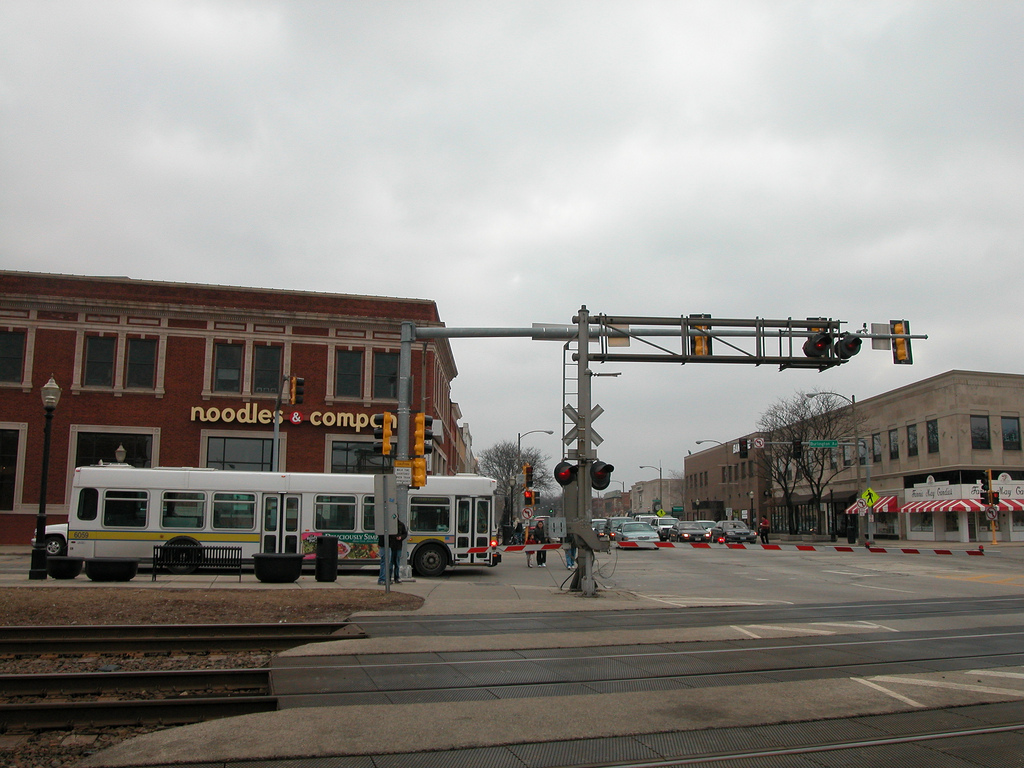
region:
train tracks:
[98, 671, 219, 710]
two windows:
[89, 337, 166, 398]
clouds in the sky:
[510, 136, 763, 295]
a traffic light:
[882, 311, 921, 366]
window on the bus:
[162, 494, 220, 529]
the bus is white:
[69, 468, 172, 551]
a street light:
[39, 362, 66, 514]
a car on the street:
[613, 510, 658, 548]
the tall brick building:
[2, 266, 480, 548]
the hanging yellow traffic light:
[375, 409, 394, 464]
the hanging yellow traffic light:
[409, 407, 433, 455]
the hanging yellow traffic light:
[408, 458, 431, 485]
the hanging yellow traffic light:
[689, 310, 713, 358]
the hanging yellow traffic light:
[889, 319, 915, 364]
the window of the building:
[883, 423, 899, 463]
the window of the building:
[902, 420, 919, 458]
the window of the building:
[925, 414, 941, 460]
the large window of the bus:
[102, 487, 150, 530]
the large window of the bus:
[159, 491, 208, 536]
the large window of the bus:
[215, 487, 260, 530]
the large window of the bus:
[317, 494, 360, 532]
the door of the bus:
[258, 487, 281, 564]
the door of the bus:
[282, 484, 302, 564]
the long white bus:
[65, 456, 502, 571]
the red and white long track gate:
[446, 535, 994, 567]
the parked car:
[667, 513, 718, 543]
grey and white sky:
[518, 5, 703, 187]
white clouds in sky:
[427, 19, 703, 187]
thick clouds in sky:
[423, 27, 654, 263]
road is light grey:
[674, 565, 887, 699]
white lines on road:
[690, 572, 900, 680]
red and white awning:
[817, 476, 1021, 527]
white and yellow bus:
[64, 425, 451, 575]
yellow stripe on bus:
[49, 507, 366, 565]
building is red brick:
[10, 287, 426, 553]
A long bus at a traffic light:
[71, 467, 502, 567]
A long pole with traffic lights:
[424, 320, 936, 368]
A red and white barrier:
[465, 538, 1012, 561]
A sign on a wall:
[193, 398, 405, 438]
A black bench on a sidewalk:
[147, 540, 250, 580]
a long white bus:
[61, 465, 498, 574]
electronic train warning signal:
[552, 458, 613, 490]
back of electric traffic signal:
[687, 310, 710, 358]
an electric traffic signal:
[520, 489, 533, 509]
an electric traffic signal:
[371, 410, 391, 453]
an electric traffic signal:
[412, 410, 435, 455]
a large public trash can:
[313, 534, 340, 580]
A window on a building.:
[253, 330, 289, 406]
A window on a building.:
[205, 342, 244, 396]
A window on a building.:
[326, 337, 365, 398]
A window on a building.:
[372, 339, 402, 400]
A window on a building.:
[116, 333, 164, 400]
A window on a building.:
[78, 321, 124, 383]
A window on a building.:
[192, 425, 266, 463]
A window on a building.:
[322, 437, 415, 480]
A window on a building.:
[3, 315, 36, 393]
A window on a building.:
[964, 409, 987, 449]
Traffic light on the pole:
[410, 416, 437, 464]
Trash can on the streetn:
[315, 531, 345, 582]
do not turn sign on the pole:
[511, 500, 540, 521]